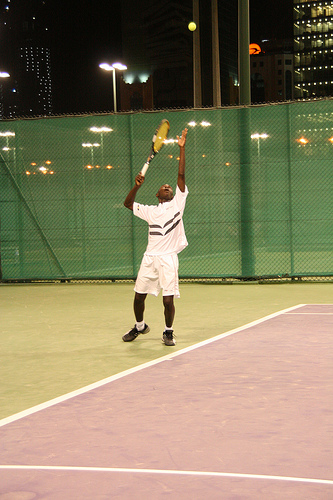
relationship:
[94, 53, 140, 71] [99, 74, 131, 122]
street light on pole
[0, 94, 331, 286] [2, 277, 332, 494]
fence around court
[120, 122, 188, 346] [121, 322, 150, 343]
man wearing shoe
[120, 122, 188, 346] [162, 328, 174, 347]
man wearing shoe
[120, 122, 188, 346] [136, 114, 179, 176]
man holding racket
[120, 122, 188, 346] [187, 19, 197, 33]
man hitting ball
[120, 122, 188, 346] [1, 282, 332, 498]
man on ground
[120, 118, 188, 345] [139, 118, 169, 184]
man with racket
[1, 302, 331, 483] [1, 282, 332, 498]
lines on ground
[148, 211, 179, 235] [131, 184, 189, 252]
stripes on shirt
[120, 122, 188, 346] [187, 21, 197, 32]
man with ball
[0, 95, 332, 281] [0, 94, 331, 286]
mesh on fence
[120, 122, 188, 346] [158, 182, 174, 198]
man looking up with face